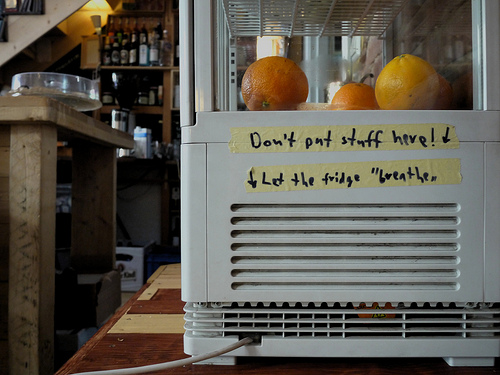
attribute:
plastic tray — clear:
[24, 57, 89, 106]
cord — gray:
[68, 335, 253, 373]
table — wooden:
[1, 85, 123, 374]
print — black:
[251, 127, 456, 147]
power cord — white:
[66, 332, 258, 374]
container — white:
[194, 12, 480, 219]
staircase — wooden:
[8, 2, 96, 65]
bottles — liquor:
[100, 12, 167, 65]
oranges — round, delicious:
[238, 54, 454, 111]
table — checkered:
[65, 250, 207, 360]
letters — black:
[246, 128, 455, 148]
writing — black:
[249, 167, 443, 187]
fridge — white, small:
[173, 1, 483, 367]